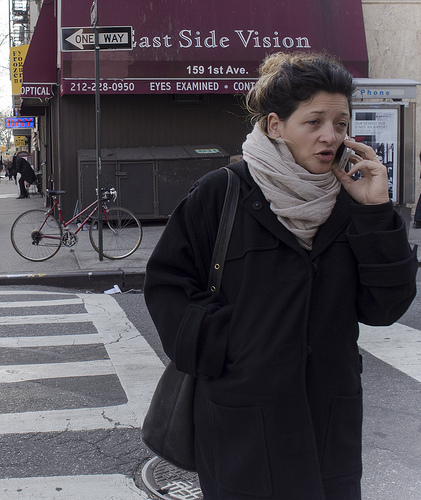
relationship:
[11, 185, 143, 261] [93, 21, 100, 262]
bike leaning against pole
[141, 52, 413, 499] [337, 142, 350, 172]
woman talking on cell phone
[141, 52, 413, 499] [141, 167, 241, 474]
woman has a purse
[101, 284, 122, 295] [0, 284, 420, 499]
trash on street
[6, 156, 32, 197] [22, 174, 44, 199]
man sitting on bench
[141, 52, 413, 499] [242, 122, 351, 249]
woman wearing a scarf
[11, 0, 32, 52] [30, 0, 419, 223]
fire escape on building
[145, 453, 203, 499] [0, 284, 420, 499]
man hole cover on street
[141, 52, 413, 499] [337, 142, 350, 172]
woman speaking on cell phone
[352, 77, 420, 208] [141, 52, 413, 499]
phone booth behind woman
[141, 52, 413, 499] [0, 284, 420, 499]
woman crossing street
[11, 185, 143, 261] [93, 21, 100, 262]
bike attached to pole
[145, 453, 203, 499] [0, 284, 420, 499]
man hole cover in street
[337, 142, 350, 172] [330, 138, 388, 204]
cell phone in hand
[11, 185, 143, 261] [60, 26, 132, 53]
bike parked under one way street sign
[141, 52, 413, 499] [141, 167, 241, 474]
woman carrying a purse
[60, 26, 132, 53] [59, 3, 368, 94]
one way street sign in front of awning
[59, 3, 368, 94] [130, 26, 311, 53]
awning reads east side vision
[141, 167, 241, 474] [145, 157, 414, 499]
purse next to coat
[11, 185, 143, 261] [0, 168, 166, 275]
bike on sidewalk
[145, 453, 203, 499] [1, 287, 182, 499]
man hole cover in pedestrian crossing